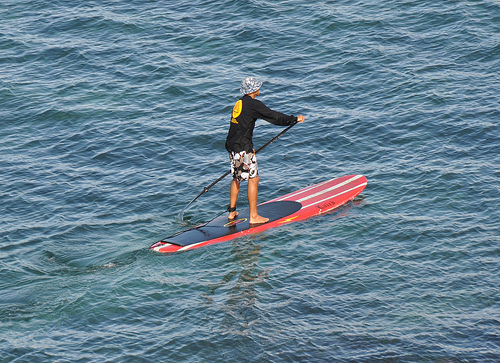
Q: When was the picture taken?
A: Daytime.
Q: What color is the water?
A: Blue.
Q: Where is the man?
A: On the surfboard.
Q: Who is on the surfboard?
A: The man.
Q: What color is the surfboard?
A: Red, white, and black.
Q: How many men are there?
A: One.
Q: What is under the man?
A: The surfboard.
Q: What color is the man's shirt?
A: Black and yellow.